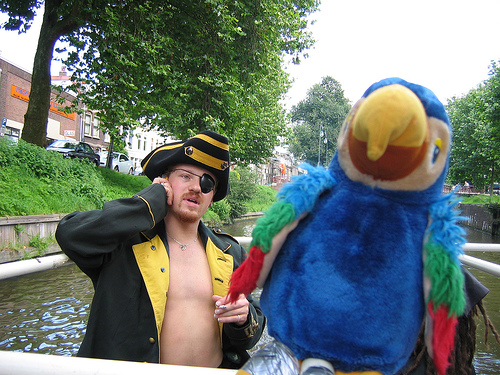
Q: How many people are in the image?
A: 1.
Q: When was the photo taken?
A: Daytime.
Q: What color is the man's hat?
A: Black and Yellow.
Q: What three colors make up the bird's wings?
A: Blue, Green, and Red.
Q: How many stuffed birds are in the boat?
A: 1.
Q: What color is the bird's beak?
A: Yellow.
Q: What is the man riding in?
A: A boat.